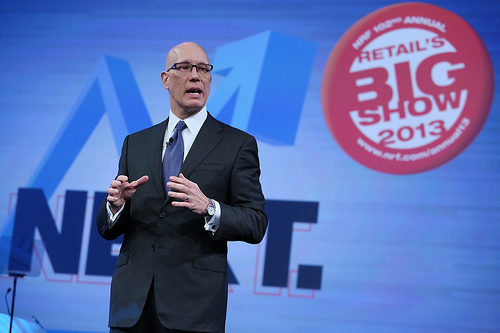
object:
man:
[95, 41, 270, 333]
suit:
[95, 105, 268, 332]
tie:
[160, 120, 188, 198]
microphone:
[165, 136, 175, 147]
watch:
[204, 197, 217, 227]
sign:
[320, 2, 497, 176]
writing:
[8, 187, 323, 291]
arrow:
[0, 29, 318, 276]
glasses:
[165, 61, 212, 75]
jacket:
[95, 109, 268, 332]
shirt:
[104, 106, 220, 236]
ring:
[182, 195, 191, 201]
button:
[209, 223, 218, 231]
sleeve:
[203, 198, 220, 235]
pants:
[108, 275, 197, 333]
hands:
[164, 173, 205, 214]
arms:
[204, 134, 268, 245]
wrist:
[201, 198, 218, 219]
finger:
[166, 190, 190, 201]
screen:
[0, 1, 500, 332]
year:
[378, 119, 447, 146]